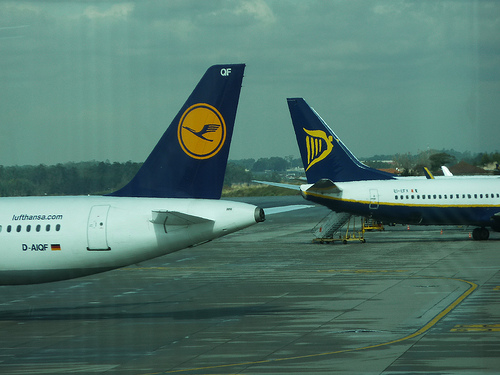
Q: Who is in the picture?
A: No one.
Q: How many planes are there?
A: Two.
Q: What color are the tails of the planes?
A: Blue and yellow.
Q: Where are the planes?
A: On the cement.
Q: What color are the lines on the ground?
A: Yellow.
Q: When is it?
A: Day time.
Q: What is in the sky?
A: Clouds.